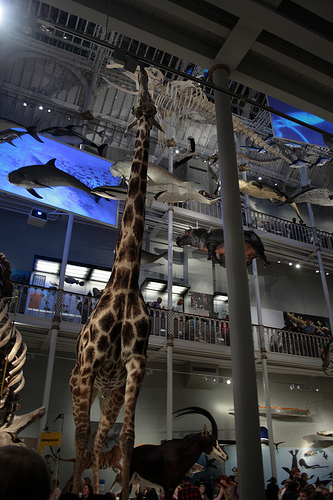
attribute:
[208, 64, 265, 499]
pillar — tan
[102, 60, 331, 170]
bones — white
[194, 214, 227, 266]
shirt — red, black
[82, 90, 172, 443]
giraffe — large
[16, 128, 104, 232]
aquarium — display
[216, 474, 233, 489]
hair — red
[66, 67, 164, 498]
giraffe — brown, tan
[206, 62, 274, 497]
pole — large, grey